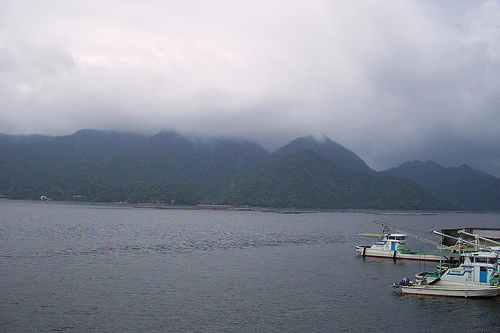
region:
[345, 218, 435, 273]
this is a ship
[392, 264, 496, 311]
this is a ship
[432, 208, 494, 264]
this is a ship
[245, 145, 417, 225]
this is a small hill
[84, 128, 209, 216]
this is a small hill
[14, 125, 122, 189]
this is a small hill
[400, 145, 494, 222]
this is a small hill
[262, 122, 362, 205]
this is a small hill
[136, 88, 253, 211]
this is a small hill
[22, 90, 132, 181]
this is a small hill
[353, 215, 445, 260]
A boat to the most left of the others.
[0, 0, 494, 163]
A white cloudy foggy sky.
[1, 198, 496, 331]
Grey calm water.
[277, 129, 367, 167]
The tallest mountain with fog on it.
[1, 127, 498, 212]
All the foggy land across the water.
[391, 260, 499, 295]
The bottom most boat with a blue door.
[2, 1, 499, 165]
A foggy white sky.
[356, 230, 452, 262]
The longest boat.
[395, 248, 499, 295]
The shorter fatter boat.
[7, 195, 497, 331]
Grey calm rippled water.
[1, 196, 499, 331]
A large body of water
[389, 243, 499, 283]
A large boat on the water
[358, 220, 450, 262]
A large boat on the water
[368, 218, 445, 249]
a crane on a boat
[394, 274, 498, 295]
A small boat on the water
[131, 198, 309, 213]
some boats on the water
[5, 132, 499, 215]
a large wooded mountain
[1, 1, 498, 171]
A grey, cloudy sky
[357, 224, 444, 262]
a large white boat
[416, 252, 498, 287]
a large white boat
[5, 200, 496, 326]
boats on the edge of a calm gray sea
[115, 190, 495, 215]
flat brown landings at the edge of water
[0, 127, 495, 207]
mountains covered with green trees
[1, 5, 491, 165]
cloudy and hazy gray skies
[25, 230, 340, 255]
line of ripples along the water surface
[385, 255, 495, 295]
flat white boat in front of boat with cabin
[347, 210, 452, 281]
boat with gray slanted beam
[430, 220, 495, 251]
silver poles slanted over pier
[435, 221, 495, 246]
low angled brown structure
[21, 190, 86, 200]
homes along the edge of water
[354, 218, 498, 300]
the marine equipment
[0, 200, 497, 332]
a large body of water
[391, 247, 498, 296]
a white and blue boat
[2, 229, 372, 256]
medium waves in the water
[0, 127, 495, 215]
many tree covered hills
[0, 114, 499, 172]
fog on the hilltops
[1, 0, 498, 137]
large whispy white clouds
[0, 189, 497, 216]
the water's far edge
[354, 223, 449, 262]
a boat with a flat front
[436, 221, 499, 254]
a boat dock